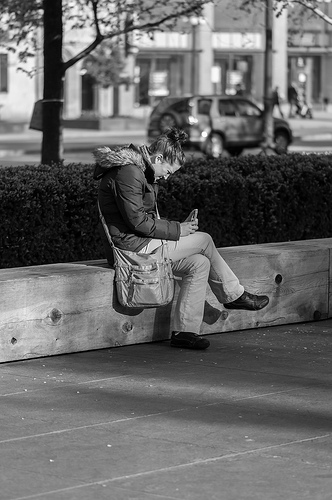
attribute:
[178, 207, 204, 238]
plate — slice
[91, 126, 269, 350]
lady — short, hooded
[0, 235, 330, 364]
plank — wooden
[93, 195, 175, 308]
purse — satchel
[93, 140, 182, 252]
coat — black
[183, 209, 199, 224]
cake — white